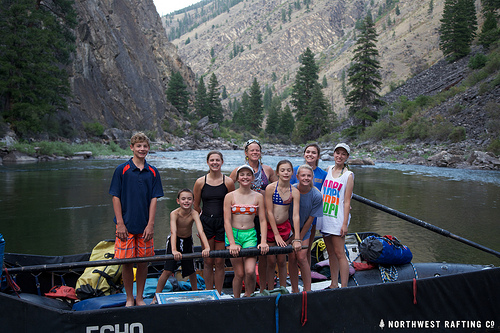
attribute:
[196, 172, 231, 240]
tank top — black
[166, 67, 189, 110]
evergreen tree — clustered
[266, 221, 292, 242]
shorts — red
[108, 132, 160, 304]
person — smiling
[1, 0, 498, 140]
trees — growing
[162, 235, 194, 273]
swim trunks — black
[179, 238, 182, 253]
drawstrings — white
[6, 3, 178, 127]
mountain — large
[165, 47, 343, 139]
trees — evergreen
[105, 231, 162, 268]
shorts — orange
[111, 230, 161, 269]
shorts — orange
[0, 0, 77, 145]
vegetation — green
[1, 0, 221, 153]
mountain — rocky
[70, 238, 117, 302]
duffel bag — yellow, black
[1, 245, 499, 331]
raft — black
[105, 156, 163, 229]
polo shirt — blue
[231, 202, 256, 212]
bikini top — orange, white, polka dotted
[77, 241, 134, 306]
duffel bag — large, yellow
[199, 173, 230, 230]
shirt — black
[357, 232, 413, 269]
bag — black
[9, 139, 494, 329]
they — standing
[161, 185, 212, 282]
boy — little 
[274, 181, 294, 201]
bikini — american flag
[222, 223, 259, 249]
shorts — bright green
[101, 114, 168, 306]
boy — wearing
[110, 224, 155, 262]
checkered shorts — orange, white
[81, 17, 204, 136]
cliff — rock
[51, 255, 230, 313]
raft — gray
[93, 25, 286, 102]
mountains — rocky